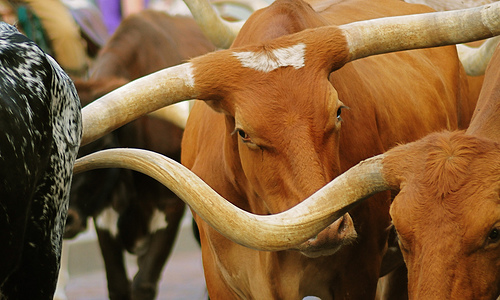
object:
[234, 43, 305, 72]
spot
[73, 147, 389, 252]
horn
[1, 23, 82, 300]
markings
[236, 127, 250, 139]
eye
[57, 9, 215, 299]
cow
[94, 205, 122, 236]
markings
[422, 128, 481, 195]
hair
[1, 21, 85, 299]
animal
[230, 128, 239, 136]
lashes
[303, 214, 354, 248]
nose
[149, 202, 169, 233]
patches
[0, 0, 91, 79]
person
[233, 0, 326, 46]
bump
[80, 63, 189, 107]
edge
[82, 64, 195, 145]
horn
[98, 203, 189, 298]
part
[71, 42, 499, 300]
bull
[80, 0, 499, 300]
bull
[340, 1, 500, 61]
horns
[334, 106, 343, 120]
eyes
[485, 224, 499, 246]
eyes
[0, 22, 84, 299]
spots